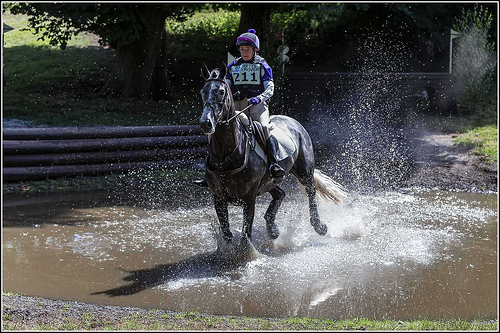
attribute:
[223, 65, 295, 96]
contestant number — white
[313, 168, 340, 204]
tail — white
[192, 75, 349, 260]
horse — black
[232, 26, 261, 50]
bonnet — purple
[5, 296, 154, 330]
stones — grey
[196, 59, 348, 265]
horse — black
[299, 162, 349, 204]
tail — horse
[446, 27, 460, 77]
flag — white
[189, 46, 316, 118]
riding outfit — purple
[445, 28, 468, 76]
flag — white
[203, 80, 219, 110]
mark — white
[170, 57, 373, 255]
horse — black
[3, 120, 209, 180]
fence — long, wooden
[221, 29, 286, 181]
player — 211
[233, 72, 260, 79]
lettering — black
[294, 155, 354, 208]
tail — white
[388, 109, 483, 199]
path — mud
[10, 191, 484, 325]
hole — water